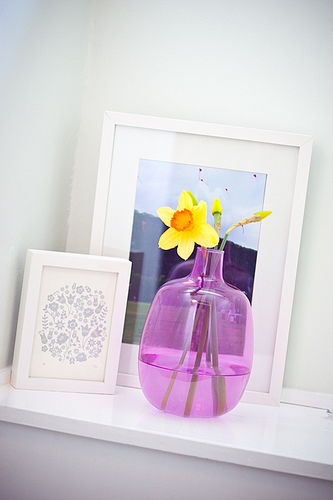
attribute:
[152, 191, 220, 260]
flower — yellow, pink, silk, artificial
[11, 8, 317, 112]
wall — light, green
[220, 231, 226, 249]
stem — green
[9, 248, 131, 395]
picture frame — white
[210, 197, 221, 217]
flower — unbloomed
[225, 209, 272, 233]
flower — unbloomed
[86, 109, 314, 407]
frame — white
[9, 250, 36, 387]
frame — white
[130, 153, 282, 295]
painting — nature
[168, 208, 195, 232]
flower — orange, yellow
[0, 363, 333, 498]
shelf — white 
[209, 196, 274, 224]
buds — yellow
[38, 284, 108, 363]
drawing — framed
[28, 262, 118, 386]
picture — framed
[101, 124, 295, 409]
picture — framed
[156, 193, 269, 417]
flower — artificial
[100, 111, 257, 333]
frame — photo